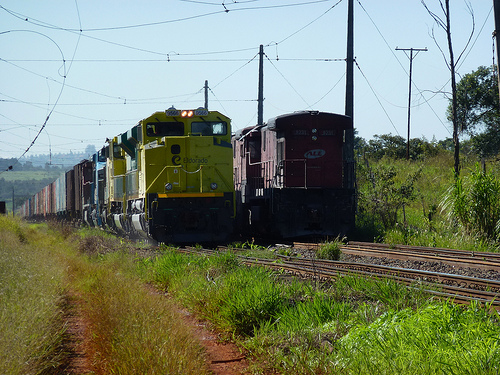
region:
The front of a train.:
[140, 106, 236, 241]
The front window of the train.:
[193, 120, 228, 135]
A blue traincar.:
[51, 173, 67, 210]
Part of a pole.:
[257, 45, 267, 125]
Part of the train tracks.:
[396, 266, 433, 293]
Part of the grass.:
[134, 306, 161, 357]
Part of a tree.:
[472, 74, 491, 106]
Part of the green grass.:
[383, 321, 439, 363]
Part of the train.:
[261, 108, 348, 185]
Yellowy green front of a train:
[139, 114, 232, 195]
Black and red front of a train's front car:
[262, 112, 353, 187]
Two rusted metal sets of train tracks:
[388, 237, 463, 301]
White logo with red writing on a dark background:
[296, 143, 331, 161]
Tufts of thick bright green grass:
[188, 268, 324, 325]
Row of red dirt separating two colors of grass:
[178, 317, 240, 369]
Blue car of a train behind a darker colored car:
[53, 171, 70, 214]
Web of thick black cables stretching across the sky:
[4, 2, 144, 155]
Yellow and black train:
[104, 105, 235, 245]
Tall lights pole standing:
[392, 44, 430, 149]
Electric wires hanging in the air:
[2, 5, 86, 66]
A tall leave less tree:
[423, 2, 477, 178]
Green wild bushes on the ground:
[202, 267, 287, 338]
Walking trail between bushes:
[41, 247, 106, 372]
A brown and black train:
[254, 104, 359, 239]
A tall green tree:
[447, 60, 499, 158]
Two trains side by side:
[126, 105, 358, 247]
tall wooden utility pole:
[341, 1, 356, 113]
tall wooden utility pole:
[255, 42, 267, 120]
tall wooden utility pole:
[201, 80, 213, 104]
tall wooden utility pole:
[404, 49, 415, 154]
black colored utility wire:
[10, 8, 258, 56]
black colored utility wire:
[11, 53, 349, 66]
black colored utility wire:
[4, 3, 339, 28]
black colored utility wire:
[6, 96, 261, 106]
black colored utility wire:
[383, 6, 498, 107]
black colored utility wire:
[359, 5, 452, 136]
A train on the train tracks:
[2, 102, 240, 252]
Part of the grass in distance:
[81, 226, 96, 234]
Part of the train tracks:
[332, 262, 357, 277]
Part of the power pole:
[256, 60, 265, 83]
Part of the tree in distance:
[466, 86, 488, 106]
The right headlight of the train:
[161, 180, 174, 190]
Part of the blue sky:
[126, 65, 155, 82]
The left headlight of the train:
[207, 178, 219, 190]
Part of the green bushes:
[399, 330, 453, 365]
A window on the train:
[186, 118, 228, 138]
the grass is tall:
[272, 292, 352, 361]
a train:
[148, 105, 235, 204]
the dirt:
[204, 330, 226, 350]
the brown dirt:
[197, 328, 227, 350]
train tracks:
[432, 279, 478, 304]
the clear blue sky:
[193, 30, 232, 42]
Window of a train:
[189, 120, 228, 135]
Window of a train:
[190, 116, 234, 138]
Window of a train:
[143, 121, 186, 137]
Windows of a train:
[141, 118, 230, 143]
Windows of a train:
[140, 118, 227, 136]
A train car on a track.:
[102, 132, 142, 237]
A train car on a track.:
[89, 150, 114, 226]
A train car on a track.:
[81, 164, 100, 231]